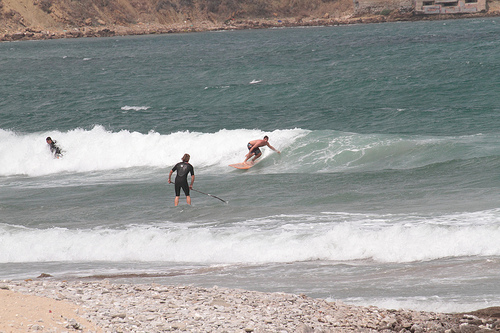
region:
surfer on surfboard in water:
[230, 113, 290, 177]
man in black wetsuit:
[156, 145, 236, 209]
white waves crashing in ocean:
[106, 124, 171, 159]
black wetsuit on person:
[164, 159, 194, 199]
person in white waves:
[35, 130, 70, 165]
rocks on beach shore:
[169, 284, 242, 322]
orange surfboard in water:
[223, 159, 270, 178]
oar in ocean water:
[201, 187, 240, 211]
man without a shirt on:
[252, 134, 278, 153]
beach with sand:
[16, 302, 76, 329]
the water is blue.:
[2, 18, 497, 131]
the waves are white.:
[1, 116, 327, 190]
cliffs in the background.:
[1, 0, 498, 43]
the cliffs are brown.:
[1, 0, 497, 42]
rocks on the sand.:
[3, 271, 487, 331]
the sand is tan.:
[1, 286, 103, 331]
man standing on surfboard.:
[225, 132, 285, 171]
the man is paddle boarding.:
[162, 147, 228, 212]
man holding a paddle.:
[164, 172, 230, 204]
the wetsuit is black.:
[166, 157, 199, 202]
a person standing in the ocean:
[167, 153, 197, 205]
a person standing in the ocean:
[44, 133, 64, 157]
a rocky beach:
[2, 271, 499, 328]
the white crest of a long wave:
[0, 221, 498, 265]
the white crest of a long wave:
[1, 127, 418, 177]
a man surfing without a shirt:
[243, 133, 275, 160]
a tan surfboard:
[233, 156, 249, 168]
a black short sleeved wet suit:
[170, 161, 195, 196]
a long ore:
[167, 177, 229, 207]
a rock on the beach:
[213, 306, 225, 312]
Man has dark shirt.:
[257, 126, 282, 168]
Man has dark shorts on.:
[236, 120, 288, 191]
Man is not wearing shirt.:
[242, 110, 299, 191]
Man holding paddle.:
[166, 177, 274, 248]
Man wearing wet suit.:
[173, 149, 235, 266]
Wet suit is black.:
[143, 155, 238, 255]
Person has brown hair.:
[172, 140, 197, 207]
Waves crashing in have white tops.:
[66, 122, 221, 195]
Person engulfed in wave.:
[32, 107, 103, 219]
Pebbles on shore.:
[168, 280, 290, 327]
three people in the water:
[46, 133, 270, 203]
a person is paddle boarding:
[166, 152, 218, 207]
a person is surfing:
[228, 132, 273, 169]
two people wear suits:
[47, 137, 231, 211]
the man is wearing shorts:
[228, 133, 279, 167]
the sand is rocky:
[0, 281, 499, 330]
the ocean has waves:
[0, 104, 498, 312]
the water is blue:
[4, 17, 495, 275]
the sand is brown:
[4, 277, 496, 331]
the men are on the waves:
[46, 132, 278, 203]